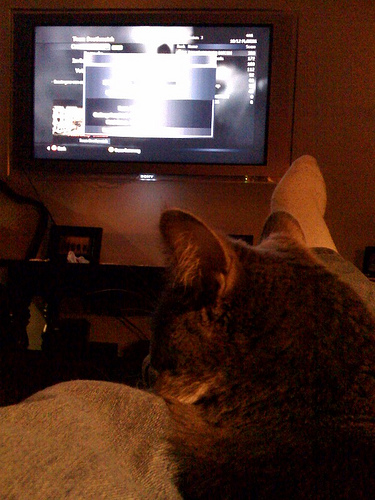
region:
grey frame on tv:
[21, 14, 280, 177]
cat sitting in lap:
[131, 189, 349, 477]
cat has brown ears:
[160, 228, 301, 280]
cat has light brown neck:
[173, 365, 218, 405]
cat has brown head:
[246, 234, 350, 405]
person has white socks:
[268, 135, 336, 256]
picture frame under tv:
[13, 216, 138, 287]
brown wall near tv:
[286, 72, 374, 148]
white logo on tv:
[133, 170, 164, 192]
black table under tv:
[16, 266, 174, 383]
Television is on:
[28, 66, 276, 165]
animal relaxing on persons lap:
[159, 210, 370, 495]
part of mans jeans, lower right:
[0, 375, 176, 495]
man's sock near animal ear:
[270, 153, 334, 243]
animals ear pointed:
[162, 209, 238, 293]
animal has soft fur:
[162, 412, 208, 499]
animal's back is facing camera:
[186, 229, 370, 431]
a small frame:
[48, 226, 101, 261]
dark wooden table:
[4, 260, 167, 350]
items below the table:
[56, 317, 145, 359]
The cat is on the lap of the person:
[90, 185, 372, 497]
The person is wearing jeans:
[19, 390, 169, 498]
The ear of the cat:
[156, 198, 236, 309]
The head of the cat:
[137, 190, 308, 409]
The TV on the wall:
[7, 7, 298, 191]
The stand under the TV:
[2, 245, 187, 377]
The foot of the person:
[261, 152, 342, 253]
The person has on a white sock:
[270, 151, 338, 256]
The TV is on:
[36, 28, 261, 149]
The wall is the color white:
[298, 19, 364, 174]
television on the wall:
[17, 9, 278, 169]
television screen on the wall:
[45, 28, 261, 153]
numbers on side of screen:
[243, 48, 256, 113]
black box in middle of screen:
[71, 51, 223, 149]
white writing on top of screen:
[61, 31, 117, 44]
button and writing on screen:
[97, 146, 142, 159]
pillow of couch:
[270, 157, 326, 241]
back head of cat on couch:
[137, 192, 329, 498]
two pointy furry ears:
[144, 192, 310, 275]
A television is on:
[11, 6, 287, 170]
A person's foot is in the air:
[273, 156, 330, 199]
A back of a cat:
[132, 201, 356, 415]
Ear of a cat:
[151, 203, 241, 308]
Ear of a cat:
[259, 204, 316, 262]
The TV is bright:
[19, 15, 274, 173]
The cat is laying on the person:
[152, 206, 338, 417]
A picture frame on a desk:
[31, 217, 104, 267]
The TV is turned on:
[15, 11, 273, 177]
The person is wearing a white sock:
[271, 148, 336, 247]